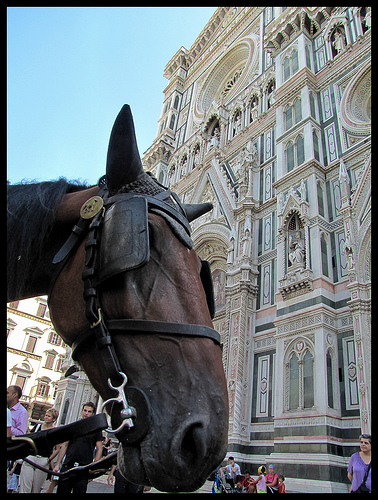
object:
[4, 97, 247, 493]
horse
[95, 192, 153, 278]
blinders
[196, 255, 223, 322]
blinders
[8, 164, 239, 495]
harness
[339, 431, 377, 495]
woman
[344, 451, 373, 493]
top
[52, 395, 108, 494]
people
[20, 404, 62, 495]
people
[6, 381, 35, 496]
people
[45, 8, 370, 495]
building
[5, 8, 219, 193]
sky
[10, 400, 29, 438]
shirt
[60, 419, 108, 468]
shirt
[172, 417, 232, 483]
nose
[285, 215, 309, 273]
statue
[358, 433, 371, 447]
hair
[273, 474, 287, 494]
people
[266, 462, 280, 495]
people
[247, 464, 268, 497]
people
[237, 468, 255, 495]
people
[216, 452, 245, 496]
people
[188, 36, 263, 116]
window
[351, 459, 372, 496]
bag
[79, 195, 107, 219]
piece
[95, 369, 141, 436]
clasp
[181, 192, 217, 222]
ear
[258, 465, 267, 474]
hat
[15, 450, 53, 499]
pants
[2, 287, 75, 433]
building